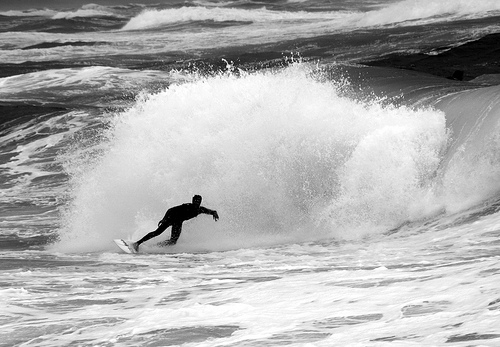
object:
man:
[130, 193, 220, 253]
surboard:
[112, 238, 139, 254]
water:
[60, 53, 99, 81]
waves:
[185, 77, 366, 176]